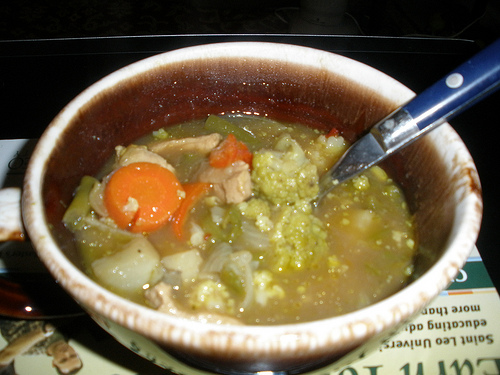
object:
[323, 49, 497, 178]
spoon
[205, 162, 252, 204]
meat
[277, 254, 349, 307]
soup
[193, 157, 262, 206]
chicken chunk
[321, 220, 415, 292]
soup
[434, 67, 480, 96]
dot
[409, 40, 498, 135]
handle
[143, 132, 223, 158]
chicken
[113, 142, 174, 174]
chicken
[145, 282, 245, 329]
chicken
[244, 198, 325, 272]
food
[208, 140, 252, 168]
carrot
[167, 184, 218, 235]
carrot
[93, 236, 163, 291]
potato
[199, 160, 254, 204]
meat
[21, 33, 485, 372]
soup bowl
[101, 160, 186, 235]
orange carrot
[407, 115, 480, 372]
white brown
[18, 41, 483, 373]
ceramic bowl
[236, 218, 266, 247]
onions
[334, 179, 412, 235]
soup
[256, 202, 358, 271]
vegetables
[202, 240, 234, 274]
onion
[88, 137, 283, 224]
carrots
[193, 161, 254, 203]
chunk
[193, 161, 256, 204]
chicken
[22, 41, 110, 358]
rim